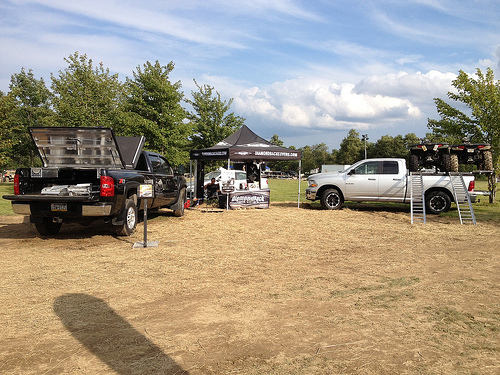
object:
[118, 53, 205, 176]
green tree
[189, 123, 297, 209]
tent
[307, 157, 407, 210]
cab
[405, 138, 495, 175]
atvs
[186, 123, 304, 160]
roof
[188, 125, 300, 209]
booth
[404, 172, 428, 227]
ladders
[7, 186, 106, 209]
tailgate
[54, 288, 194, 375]
shadow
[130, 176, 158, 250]
sign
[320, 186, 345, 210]
wheel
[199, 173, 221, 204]
man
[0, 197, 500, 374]
dirt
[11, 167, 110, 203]
bed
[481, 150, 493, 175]
wheels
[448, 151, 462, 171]
dirt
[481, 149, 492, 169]
dirt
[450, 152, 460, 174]
wheels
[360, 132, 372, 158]
light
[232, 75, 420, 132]
clouds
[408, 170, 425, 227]
ramp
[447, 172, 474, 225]
ramp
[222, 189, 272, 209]
table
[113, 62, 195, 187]
tree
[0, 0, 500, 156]
sky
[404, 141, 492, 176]
four wheeler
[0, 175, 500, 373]
ground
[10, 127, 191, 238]
pickup truck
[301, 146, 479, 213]
truck